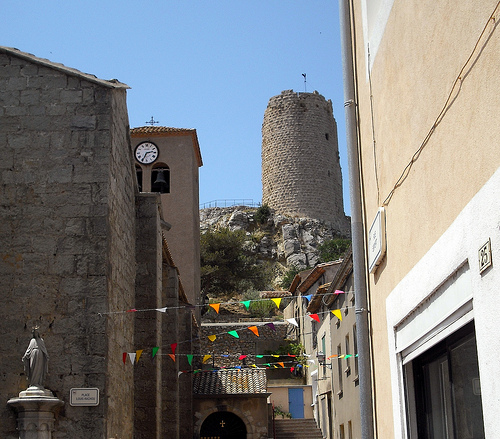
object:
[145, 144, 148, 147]
numerals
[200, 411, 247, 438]
door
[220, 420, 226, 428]
cross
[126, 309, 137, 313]
flag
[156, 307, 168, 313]
flag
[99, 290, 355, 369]
rope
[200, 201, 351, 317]
grass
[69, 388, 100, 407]
sign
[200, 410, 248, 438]
doorway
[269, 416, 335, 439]
street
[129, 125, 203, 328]
tower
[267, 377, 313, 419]
building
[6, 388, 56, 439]
stand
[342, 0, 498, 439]
building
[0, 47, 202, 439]
building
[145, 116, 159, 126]
cross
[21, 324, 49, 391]
statue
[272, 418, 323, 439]
stairway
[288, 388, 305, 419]
door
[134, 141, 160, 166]
clock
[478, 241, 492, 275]
number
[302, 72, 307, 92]
flags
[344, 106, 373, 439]
pipe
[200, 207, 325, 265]
rock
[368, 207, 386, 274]
sign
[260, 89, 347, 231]
castle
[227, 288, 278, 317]
hill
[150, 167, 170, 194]
bell